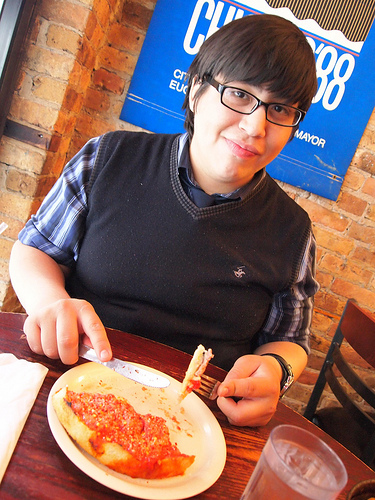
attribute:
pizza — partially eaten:
[70, 379, 202, 480]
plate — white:
[45, 338, 237, 499]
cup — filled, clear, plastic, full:
[236, 411, 356, 499]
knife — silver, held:
[35, 321, 177, 398]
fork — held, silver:
[193, 369, 238, 406]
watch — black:
[256, 348, 299, 406]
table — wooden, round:
[0, 301, 374, 499]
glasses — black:
[203, 73, 311, 133]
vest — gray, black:
[84, 113, 310, 392]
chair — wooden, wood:
[304, 290, 375, 465]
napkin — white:
[0, 338, 54, 500]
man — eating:
[6, 10, 327, 431]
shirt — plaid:
[10, 134, 320, 359]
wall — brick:
[0, 2, 373, 376]